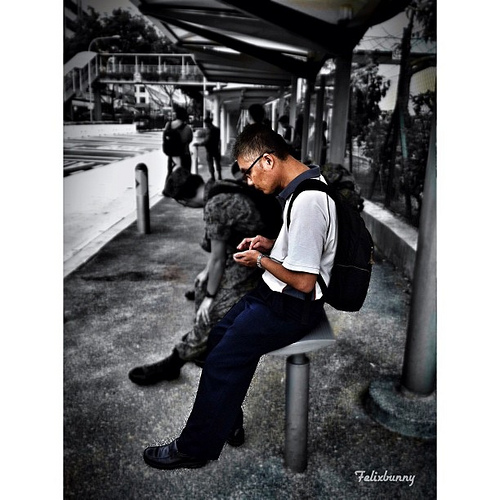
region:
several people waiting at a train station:
[126, 100, 390, 477]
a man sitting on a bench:
[231, 125, 388, 370]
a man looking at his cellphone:
[228, 124, 293, 281]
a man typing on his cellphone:
[225, 120, 294, 274]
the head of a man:
[225, 124, 292, 207]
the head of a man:
[159, 167, 208, 212]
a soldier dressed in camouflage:
[128, 163, 235, 386]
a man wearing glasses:
[227, 120, 294, 201]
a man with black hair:
[226, 120, 295, 208]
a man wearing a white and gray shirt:
[233, 112, 358, 307]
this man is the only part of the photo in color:
[134, 122, 377, 477]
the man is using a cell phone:
[227, 235, 265, 267]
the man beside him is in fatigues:
[128, 167, 268, 389]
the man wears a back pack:
[285, 165, 372, 314]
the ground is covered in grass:
[67, 213, 401, 499]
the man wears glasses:
[236, 151, 276, 181]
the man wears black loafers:
[134, 416, 264, 477]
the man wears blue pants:
[178, 277, 333, 457]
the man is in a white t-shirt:
[266, 185, 332, 302]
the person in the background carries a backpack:
[161, 117, 194, 162]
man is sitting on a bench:
[298, 327, 338, 348]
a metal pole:
[284, 367, 310, 462]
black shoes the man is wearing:
[136, 441, 183, 463]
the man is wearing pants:
[207, 348, 244, 386]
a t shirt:
[293, 210, 319, 270]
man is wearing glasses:
[240, 162, 255, 177]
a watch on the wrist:
[255, 253, 266, 263]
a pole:
[133, 163, 149, 229]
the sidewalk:
[83, 170, 114, 212]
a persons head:
[160, 173, 215, 208]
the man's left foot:
[136, 438, 213, 472]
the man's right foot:
[227, 425, 247, 449]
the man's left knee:
[199, 351, 236, 380]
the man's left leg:
[184, 377, 241, 447]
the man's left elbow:
[295, 269, 318, 296]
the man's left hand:
[231, 245, 260, 272]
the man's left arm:
[255, 254, 293, 289]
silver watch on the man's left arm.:
[253, 250, 265, 272]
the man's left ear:
[261, 152, 276, 170]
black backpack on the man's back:
[282, 167, 375, 315]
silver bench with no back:
[264, 301, 342, 474]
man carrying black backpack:
[140, 120, 377, 472]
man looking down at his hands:
[136, 124, 381, 476]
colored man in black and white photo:
[137, 125, 375, 473]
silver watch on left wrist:
[251, 248, 268, 269]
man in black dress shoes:
[141, 382, 249, 469]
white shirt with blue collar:
[255, 163, 344, 305]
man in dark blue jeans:
[136, 285, 330, 476]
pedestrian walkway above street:
[63, 48, 367, 156]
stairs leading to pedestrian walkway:
[63, 48, 100, 124]